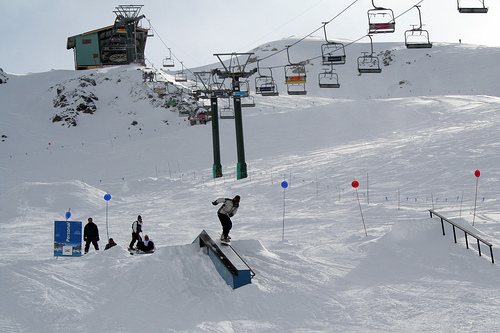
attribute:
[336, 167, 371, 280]
stick — Red circle 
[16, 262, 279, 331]
snow — white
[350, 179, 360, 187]
circle — red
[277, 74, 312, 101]
chair — metal ski lift 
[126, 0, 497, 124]
ski lift — metal, metal ski lift 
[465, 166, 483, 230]
circle stick — red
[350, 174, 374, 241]
circle stick — red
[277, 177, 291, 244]
circle stick — red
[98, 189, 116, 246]
circle stick — red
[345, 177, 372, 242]
stick — Red circle 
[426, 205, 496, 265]
fence — small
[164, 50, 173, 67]
chair — metal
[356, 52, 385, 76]
lift — metal ski lift 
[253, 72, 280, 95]
chair — metal ski lift 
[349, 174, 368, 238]
stick — red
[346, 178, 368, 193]
red circle —  Red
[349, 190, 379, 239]
stick — with circle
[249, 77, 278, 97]
lift — metal ski lift 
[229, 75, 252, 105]
chair — metal ski lift 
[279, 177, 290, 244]
stick — blue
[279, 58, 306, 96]
chair — metal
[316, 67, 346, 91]
chair — metal ski lift 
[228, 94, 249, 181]
metal pole —  Large ,  green,  metal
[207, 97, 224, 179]
metal pole —  Large ,  green,  metal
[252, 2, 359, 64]
ski-lift wire —  for ski lift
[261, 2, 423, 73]
ski-lift wire —  for ski lift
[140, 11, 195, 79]
ski-lift wire —  for ski lift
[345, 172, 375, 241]
stick — Red circle 